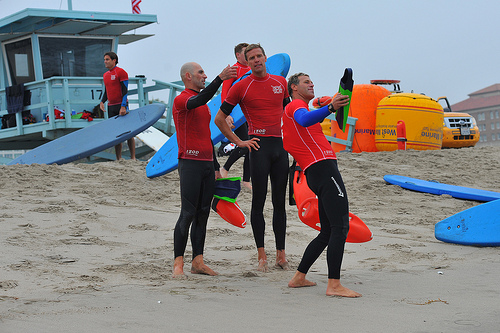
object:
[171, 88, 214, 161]
tops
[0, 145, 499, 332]
beach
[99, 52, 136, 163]
man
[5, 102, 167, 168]
board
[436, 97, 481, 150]
vehicle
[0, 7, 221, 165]
building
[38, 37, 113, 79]
windows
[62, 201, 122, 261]
footprints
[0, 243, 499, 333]
sand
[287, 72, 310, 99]
hair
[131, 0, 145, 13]
flag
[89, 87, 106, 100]
number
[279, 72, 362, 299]
man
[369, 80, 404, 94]
object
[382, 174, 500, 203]
surfboard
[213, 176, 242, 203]
shoe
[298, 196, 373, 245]
float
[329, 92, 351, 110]
hand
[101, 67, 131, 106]
shirt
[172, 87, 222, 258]
wetsuit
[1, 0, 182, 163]
stand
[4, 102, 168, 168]
surfboard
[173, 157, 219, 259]
pants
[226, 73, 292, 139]
shirts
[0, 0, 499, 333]
picture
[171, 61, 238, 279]
lifeguards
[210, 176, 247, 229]
life perservers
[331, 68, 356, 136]
flipper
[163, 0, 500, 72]
sky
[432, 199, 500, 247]
surfboards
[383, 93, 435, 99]
roof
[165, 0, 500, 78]
clouds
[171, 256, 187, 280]
feet